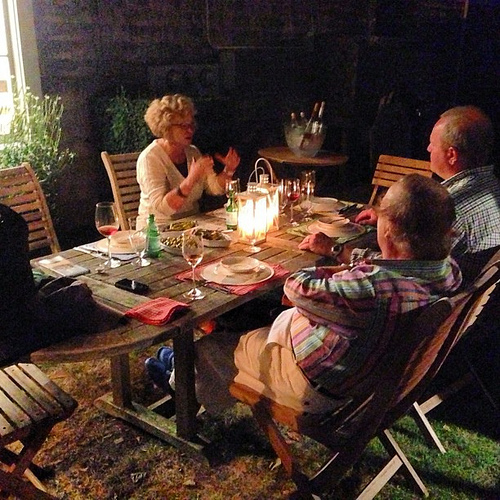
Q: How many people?
A: Three.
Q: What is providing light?
A: Lantern.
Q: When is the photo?
A: Night time.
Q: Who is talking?
A: Woman.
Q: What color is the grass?
A: Green.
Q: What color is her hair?
A: Blonde.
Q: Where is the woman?
A: Left side of table.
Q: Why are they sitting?
A: To eat.